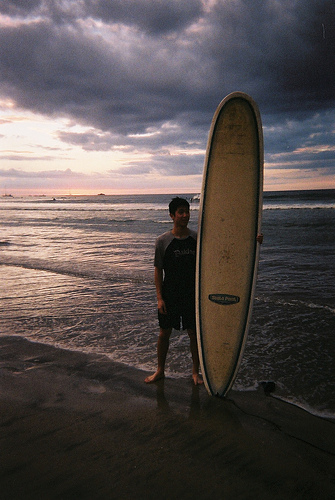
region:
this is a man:
[148, 196, 201, 385]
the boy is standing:
[143, 192, 196, 378]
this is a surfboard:
[196, 87, 265, 398]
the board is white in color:
[209, 180, 258, 239]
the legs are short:
[158, 340, 197, 376]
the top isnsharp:
[218, 88, 254, 126]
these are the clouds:
[69, 25, 182, 114]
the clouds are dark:
[41, 32, 161, 120]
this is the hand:
[151, 265, 166, 313]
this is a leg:
[145, 327, 173, 378]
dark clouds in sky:
[2, 2, 333, 190]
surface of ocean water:
[3, 190, 332, 407]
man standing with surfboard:
[145, 90, 264, 398]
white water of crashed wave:
[265, 202, 332, 212]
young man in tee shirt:
[146, 197, 198, 387]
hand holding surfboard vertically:
[195, 89, 265, 395]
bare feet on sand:
[142, 370, 204, 383]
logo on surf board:
[207, 291, 239, 304]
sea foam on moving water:
[66, 309, 164, 365]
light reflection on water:
[0, 227, 90, 320]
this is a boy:
[140, 194, 198, 376]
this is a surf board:
[195, 92, 277, 331]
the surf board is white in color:
[196, 98, 252, 392]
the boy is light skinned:
[150, 330, 205, 383]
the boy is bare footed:
[144, 327, 199, 390]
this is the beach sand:
[8, 361, 111, 497]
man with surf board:
[112, 92, 288, 437]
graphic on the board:
[208, 284, 236, 305]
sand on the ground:
[11, 361, 271, 479]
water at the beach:
[0, 202, 302, 347]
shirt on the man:
[147, 230, 191, 279]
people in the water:
[168, 181, 193, 200]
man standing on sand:
[145, 186, 201, 385]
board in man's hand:
[192, 82, 261, 405]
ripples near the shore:
[23, 249, 113, 320]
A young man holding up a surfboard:
[135, 83, 269, 405]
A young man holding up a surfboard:
[141, 87, 270, 406]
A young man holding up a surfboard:
[137, 87, 271, 408]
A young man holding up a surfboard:
[135, 86, 268, 419]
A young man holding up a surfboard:
[140, 87, 270, 399]